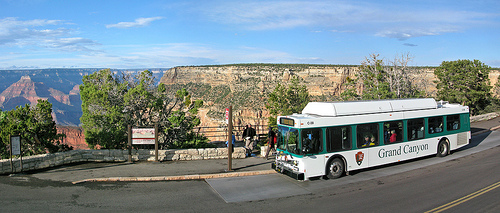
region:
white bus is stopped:
[276, 95, 471, 180]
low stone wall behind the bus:
[1, 149, 274, 172]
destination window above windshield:
[278, 118, 295, 127]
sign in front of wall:
[5, 133, 22, 173]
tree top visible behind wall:
[75, 69, 205, 147]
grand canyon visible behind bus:
[0, 67, 497, 147]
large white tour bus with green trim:
[269, 93, 476, 187]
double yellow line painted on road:
[412, 171, 497, 211]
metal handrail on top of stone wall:
[150, 115, 277, 147]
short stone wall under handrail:
[37, 141, 268, 163]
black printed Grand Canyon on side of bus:
[376, 137, 437, 165]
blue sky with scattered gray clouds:
[2, 3, 499, 73]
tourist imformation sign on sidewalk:
[129, 118, 161, 166]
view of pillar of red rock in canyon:
[0, 71, 68, 112]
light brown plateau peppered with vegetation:
[153, 61, 498, 112]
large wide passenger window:
[323, 125, 358, 153]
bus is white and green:
[274, 93, 471, 180]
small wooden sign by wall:
[10, 133, 25, 174]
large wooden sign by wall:
[127, 122, 158, 161]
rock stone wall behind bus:
[1, 110, 499, 173]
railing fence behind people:
[181, 123, 278, 149]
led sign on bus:
[279, 118, 294, 126]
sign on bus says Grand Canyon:
[377, 142, 431, 162]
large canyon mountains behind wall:
[1, 66, 498, 148]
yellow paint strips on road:
[427, 183, 499, 212]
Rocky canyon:
[0, 62, 495, 159]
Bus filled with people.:
[270, 96, 470, 181]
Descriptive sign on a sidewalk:
[125, 125, 156, 162]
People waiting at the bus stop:
[225, 121, 278, 158]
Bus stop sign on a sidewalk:
[222, 105, 232, 171]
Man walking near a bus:
[261, 125, 276, 160]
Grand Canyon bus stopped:
[270, 95, 470, 175]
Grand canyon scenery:
[0, 60, 495, 155]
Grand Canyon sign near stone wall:
[6, 132, 21, 172]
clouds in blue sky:
[0, 2, 497, 67]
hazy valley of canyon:
[2, 67, 171, 123]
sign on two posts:
[127, 123, 160, 163]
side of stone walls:
[1, 145, 273, 181]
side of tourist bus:
[274, 95, 471, 180]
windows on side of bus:
[305, 114, 460, 151]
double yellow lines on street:
[418, 181, 498, 211]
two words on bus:
[378, 140, 429, 160]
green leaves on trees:
[82, 69, 202, 147]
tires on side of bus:
[327, 139, 450, 177]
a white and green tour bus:
[274, 97, 469, 182]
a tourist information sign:
[124, 122, 159, 162]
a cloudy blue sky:
[2, 0, 499, 68]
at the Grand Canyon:
[0, 67, 497, 158]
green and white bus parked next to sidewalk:
[265, 93, 475, 185]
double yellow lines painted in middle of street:
[421, 182, 498, 212]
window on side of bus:
[354, 119, 382, 151]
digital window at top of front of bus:
[277, 115, 298, 129]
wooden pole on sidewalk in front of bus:
[225, 103, 240, 173]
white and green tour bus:
[267, 96, 472, 183]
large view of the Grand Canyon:
[1, 63, 498, 153]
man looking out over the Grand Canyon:
[240, 124, 256, 154]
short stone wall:
[0, 147, 247, 177]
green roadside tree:
[432, 58, 492, 115]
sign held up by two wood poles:
[126, 122, 158, 160]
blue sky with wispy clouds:
[2, 0, 497, 66]